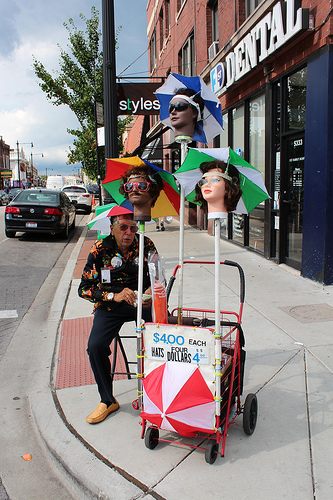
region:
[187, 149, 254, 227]
A dummy cartoon head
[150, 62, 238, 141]
A dummy cartoon head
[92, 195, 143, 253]
A dummy cartoon head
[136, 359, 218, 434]
A small open umbrella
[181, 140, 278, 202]
A small open umbrella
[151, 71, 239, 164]
A small open umbrella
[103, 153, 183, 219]
A small open umbrella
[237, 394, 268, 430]
A black trolley wheel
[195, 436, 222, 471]
A black trolley wheel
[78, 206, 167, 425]
An old man on a street corner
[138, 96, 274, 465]
A street vendor's cart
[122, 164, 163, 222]
A mannequin head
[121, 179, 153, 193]
A pair of red sunglasses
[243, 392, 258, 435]
The back wheel of a cart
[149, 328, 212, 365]
A sale sign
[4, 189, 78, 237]
A parked black car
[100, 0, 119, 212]
A black light post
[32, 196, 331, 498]
A concrete sidewalk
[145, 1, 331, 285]
A brick building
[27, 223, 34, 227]
TAG ON THE CAR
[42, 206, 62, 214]
LIGHTS ON THE BACK OF CAR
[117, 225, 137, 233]
MAN HAS ON SUN GLASSES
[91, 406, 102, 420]
MAN WEARING BROWN LOAFS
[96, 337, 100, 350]
MAN HAS ON BLACK PANTS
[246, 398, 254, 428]
BLACK WHEEL ON THE CART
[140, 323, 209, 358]
SIGN ON THE CART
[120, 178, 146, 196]
SUN GLASSES ON THE FACE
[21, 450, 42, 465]
PAPER ON THE GROUND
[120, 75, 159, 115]
SIGN ON THE POLE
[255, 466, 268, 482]
part of a floor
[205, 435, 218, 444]
part of a wheel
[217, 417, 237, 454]
part fo a post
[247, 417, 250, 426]
part f a wheel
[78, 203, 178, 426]
man sitting down on chair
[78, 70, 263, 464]
man selling umbrella hats on sidewalk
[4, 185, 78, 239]
car parked on side of street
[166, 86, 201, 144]
mannequin head wearing sun glasses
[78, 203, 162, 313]
person wearing an authorization badge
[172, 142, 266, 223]
umbrella is green and white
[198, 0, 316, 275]
shop storefront has dental sign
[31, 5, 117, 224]
tree is tall with green leaves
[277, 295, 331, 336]
man hole on sidewalk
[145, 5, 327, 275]
building made of red bricks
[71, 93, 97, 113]
green leaves on the tree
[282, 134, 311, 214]
a window on the building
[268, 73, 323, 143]
a window on the building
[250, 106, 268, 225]
a window on the building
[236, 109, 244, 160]
a window on the building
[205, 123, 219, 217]
a window on the building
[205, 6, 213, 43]
a window on the building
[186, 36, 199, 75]
a window on the building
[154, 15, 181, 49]
a window on the building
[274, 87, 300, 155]
a window on the building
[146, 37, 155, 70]
a window on a building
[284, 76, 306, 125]
a window on a building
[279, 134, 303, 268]
a window on a building